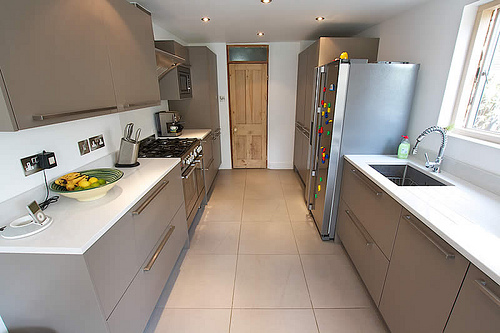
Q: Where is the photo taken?
A: Kitchen.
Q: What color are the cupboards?
A: Grey.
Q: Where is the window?
A: On right.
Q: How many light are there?
A: 4.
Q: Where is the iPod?
A: In charger on left.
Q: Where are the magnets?
A: On refrigerator.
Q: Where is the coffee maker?
A: Beyond stove.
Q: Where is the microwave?
A: Above coffee maker.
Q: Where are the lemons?
A: In bowl on left.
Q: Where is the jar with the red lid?
A: On right.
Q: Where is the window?
A: Above the sink.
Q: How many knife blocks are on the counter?
A: One.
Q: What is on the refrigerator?
A: Magnets.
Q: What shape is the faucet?
A: It is curved.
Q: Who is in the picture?
A: No one.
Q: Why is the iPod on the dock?
A: It is charging.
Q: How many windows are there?
A: One.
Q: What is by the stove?
A: The knives.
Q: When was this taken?
A: Daytime.